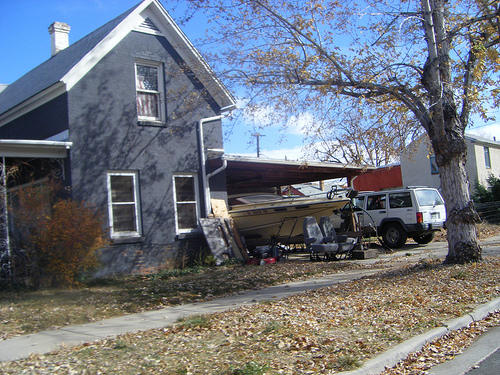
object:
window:
[482, 143, 495, 171]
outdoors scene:
[0, 0, 497, 375]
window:
[132, 62, 171, 125]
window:
[104, 168, 138, 241]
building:
[0, 0, 499, 288]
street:
[0, 217, 500, 375]